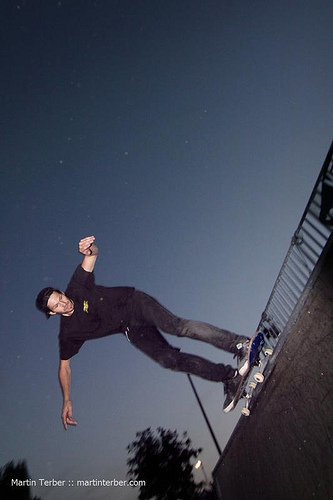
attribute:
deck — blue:
[221, 331, 265, 414]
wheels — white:
[240, 348, 273, 416]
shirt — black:
[50, 263, 134, 360]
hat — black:
[34, 285, 53, 318]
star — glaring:
[54, 153, 67, 167]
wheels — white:
[231, 345, 279, 417]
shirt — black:
[60, 268, 155, 360]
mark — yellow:
[81, 300, 88, 313]